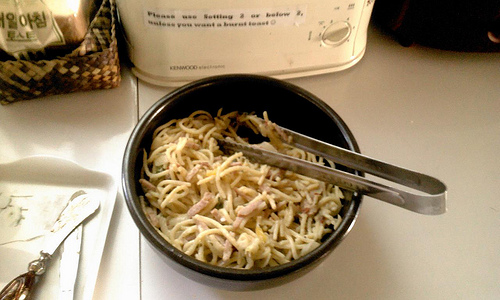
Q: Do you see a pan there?
A: No, there are no pans.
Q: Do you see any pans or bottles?
A: No, there are no pans or bottles.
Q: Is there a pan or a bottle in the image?
A: No, there are no pans or bottles.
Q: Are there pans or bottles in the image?
A: No, there are no pans or bottles.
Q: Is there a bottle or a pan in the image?
A: No, there are no pans or bottles.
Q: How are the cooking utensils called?
A: The cooking utensils are tongs.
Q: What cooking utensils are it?
A: The cooking utensils are tongs.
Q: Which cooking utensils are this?
A: These are tongs.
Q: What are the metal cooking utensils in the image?
A: The cooking utensils are tongs.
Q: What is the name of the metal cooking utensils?
A: The cooking utensils are tongs.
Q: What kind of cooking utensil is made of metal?
A: The cooking utensil is tongs.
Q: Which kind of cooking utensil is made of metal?
A: The cooking utensil is tongs.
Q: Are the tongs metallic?
A: Yes, the tongs are metallic.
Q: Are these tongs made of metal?
A: Yes, the tongs are made of metal.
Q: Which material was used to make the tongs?
A: The tongs are made of metal.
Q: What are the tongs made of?
A: The tongs are made of metal.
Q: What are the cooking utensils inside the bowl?
A: The cooking utensils are tongs.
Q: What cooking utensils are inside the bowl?
A: The cooking utensils are tongs.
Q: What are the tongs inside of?
A: The tongs are inside the bowl.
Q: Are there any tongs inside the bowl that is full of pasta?
A: Yes, there are tongs inside the bowl.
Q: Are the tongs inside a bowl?
A: Yes, the tongs are inside a bowl.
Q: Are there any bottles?
A: No, there are no bottles.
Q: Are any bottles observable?
A: No, there are no bottles.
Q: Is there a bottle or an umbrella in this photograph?
A: No, there are no bottles or umbrellas.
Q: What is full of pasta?
A: The bowl is full of pasta.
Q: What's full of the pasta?
A: The bowl is full of pasta.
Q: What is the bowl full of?
A: The bowl is full of pasta.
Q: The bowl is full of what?
A: The bowl is full of pasta.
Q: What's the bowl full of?
A: The bowl is full of pasta.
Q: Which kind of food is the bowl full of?
A: The bowl is full of pasta.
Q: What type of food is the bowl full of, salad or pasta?
A: The bowl is full of pasta.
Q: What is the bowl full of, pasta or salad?
A: The bowl is full of pasta.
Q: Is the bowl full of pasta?
A: Yes, the bowl is full of pasta.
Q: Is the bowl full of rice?
A: No, the bowl is full of pasta.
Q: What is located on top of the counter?
A: The bowl is on top of the counter.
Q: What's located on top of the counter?
A: The bowl is on top of the counter.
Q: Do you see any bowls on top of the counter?
A: Yes, there is a bowl on top of the counter.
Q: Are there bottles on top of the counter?
A: No, there is a bowl on top of the counter.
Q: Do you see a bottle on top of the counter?
A: No, there is a bowl on top of the counter.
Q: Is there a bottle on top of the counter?
A: No, there is a bowl on top of the counter.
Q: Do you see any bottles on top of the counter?
A: No, there is a bowl on top of the counter.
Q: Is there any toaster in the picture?
A: Yes, there is a toaster.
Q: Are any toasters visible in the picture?
A: Yes, there is a toaster.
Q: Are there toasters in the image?
A: Yes, there is a toaster.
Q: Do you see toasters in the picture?
A: Yes, there is a toaster.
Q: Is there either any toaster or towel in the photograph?
A: Yes, there is a toaster.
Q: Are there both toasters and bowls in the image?
A: Yes, there are both a toaster and a bowl.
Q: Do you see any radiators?
A: No, there are no radiators.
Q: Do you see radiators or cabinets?
A: No, there are no radiators or cabinets.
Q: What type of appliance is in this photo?
A: The appliance is a toaster.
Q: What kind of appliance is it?
A: The appliance is a toaster.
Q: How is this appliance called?
A: This is a toaster.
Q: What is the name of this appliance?
A: This is a toaster.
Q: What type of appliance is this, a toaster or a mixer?
A: This is a toaster.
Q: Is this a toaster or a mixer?
A: This is a toaster.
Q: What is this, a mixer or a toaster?
A: This is a toaster.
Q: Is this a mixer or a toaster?
A: This is a toaster.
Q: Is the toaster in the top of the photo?
A: Yes, the toaster is in the top of the image.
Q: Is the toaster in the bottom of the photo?
A: No, the toaster is in the top of the image.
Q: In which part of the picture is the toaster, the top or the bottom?
A: The toaster is in the top of the image.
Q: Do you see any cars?
A: No, there are no cars.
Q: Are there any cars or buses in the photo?
A: No, there are no cars or buses.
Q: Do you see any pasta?
A: Yes, there is pasta.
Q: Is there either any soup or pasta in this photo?
A: Yes, there is pasta.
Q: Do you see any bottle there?
A: No, there are no bottles.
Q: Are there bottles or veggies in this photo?
A: No, there are no bottles or veggies.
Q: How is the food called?
A: The food is pasta.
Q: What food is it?
A: The food is pasta.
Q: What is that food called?
A: This is pasta.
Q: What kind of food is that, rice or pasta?
A: This is pasta.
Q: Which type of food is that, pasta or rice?
A: This is pasta.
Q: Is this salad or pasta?
A: This is pasta.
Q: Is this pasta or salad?
A: This is pasta.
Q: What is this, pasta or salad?
A: This is pasta.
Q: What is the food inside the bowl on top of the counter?
A: The food is pasta.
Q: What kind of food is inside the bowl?
A: The food is pasta.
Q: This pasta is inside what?
A: The pasta is inside the bowl.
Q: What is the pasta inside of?
A: The pasta is inside the bowl.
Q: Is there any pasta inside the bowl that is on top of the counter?
A: Yes, there is pasta inside the bowl.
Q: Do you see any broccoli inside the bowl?
A: No, there is pasta inside the bowl.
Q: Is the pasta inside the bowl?
A: Yes, the pasta is inside the bowl.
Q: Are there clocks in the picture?
A: No, there are no clocks.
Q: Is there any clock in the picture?
A: No, there are no clocks.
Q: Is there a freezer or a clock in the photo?
A: No, there are no clocks or refrigerators.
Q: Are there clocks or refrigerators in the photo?
A: No, there are no clocks or refrigerators.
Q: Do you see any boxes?
A: No, there are no boxes.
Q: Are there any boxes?
A: No, there are no boxes.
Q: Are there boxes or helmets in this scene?
A: No, there are no boxes or helmets.